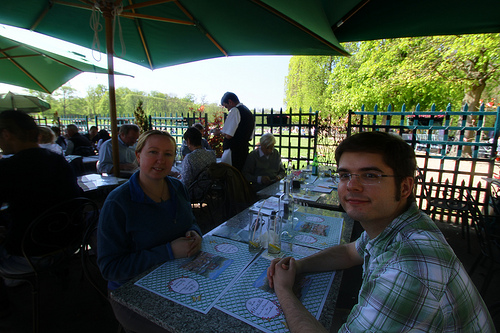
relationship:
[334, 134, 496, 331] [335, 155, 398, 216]
man has face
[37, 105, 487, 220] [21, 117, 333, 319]
fence enclosing dining area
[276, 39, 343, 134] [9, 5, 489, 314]
tree outside of restaurant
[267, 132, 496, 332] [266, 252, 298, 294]
guy has hands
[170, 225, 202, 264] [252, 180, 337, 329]
hands on table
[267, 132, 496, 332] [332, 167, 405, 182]
guy wearing glasses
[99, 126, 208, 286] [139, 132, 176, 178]
woman has face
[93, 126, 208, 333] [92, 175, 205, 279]
woman wearing top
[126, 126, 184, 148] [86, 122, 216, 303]
hair of woman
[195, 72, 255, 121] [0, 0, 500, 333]
ground covering ground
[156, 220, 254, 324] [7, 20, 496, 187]
mat at restaurant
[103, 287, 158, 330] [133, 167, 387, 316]
edge of table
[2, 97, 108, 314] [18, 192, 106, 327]
man in chair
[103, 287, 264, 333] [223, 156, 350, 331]
edge of table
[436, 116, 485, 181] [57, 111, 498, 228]
part of fence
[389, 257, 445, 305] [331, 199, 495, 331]
part of shirt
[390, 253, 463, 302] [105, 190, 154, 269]
part of sweater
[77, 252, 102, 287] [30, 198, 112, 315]
part of chair